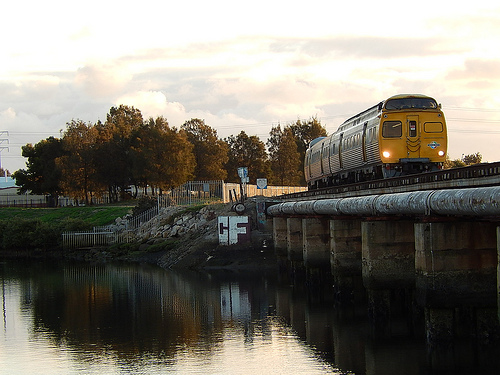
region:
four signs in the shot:
[229, 167, 280, 217]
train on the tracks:
[242, 96, 499, 201]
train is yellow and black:
[297, 86, 457, 191]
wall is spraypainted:
[209, 211, 259, 252]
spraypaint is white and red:
[215, 215, 256, 250]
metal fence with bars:
[58, 179, 235, 255]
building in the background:
[0, 178, 168, 215]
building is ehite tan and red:
[0, 177, 167, 210]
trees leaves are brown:
[12, 103, 484, 208]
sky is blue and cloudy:
[0, 0, 499, 175]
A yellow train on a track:
[273, 89, 460, 209]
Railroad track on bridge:
[263, 151, 488, 283]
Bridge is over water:
[287, 187, 462, 372]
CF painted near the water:
[207, 208, 255, 262]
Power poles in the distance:
[0, 127, 18, 172]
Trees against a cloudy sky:
[33, 102, 193, 191]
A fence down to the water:
[69, 174, 221, 245]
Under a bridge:
[355, 223, 425, 311]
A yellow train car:
[336, 104, 441, 169]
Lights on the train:
[364, 140, 449, 174]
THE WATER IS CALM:
[1, 230, 488, 374]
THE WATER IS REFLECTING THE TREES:
[8, 255, 273, 373]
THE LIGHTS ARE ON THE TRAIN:
[375, 140, 450, 173]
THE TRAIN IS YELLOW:
[283, 90, 455, 198]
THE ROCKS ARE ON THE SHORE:
[96, 196, 262, 246]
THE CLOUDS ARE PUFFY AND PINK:
[1, 11, 498, 161]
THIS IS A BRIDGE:
[251, 171, 498, 320]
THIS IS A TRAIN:
[289, 90, 464, 188]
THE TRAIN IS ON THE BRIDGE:
[256, 175, 488, 287]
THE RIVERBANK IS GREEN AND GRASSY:
[3, 200, 150, 245]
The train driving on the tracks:
[296, 90, 452, 192]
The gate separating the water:
[45, 176, 225, 246]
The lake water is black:
[19, 268, 363, 365]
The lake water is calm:
[21, 271, 352, 368]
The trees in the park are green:
[8, 103, 195, 200]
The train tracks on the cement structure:
[243, 160, 499, 200]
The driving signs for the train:
[233, 156, 272, 198]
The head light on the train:
[379, 145, 394, 161]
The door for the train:
[400, 110, 425, 161]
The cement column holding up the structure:
[350, 220, 414, 289]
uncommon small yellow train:
[296, 83, 465, 198]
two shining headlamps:
[376, 145, 447, 168]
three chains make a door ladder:
[400, 130, 421, 158]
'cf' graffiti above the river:
[211, 208, 251, 254]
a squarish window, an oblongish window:
[376, 115, 446, 146]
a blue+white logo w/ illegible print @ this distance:
[420, 136, 440, 148]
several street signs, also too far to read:
[231, 162, 269, 199]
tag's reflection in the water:
[210, 276, 260, 326]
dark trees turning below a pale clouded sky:
[12, 100, 330, 205]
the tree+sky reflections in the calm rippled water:
[21, 257, 282, 372]